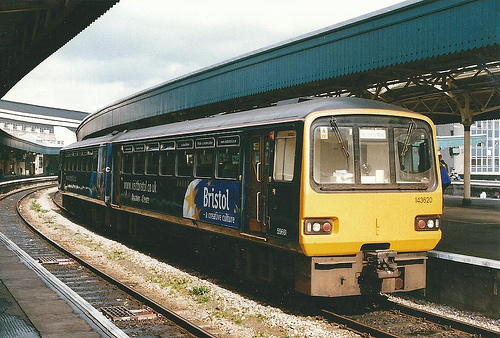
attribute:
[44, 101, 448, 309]
train — waiting, blue, yellow, passenger train, commuter train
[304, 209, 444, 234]
headlights — on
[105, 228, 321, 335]
rocks — white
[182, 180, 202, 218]
stars — gold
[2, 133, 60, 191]
platform — for train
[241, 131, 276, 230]
door — access door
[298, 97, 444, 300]
front — yellow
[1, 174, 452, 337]
tracks — curved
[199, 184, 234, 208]
words — bristol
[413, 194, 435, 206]
number — identification numbe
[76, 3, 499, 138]
roof — green